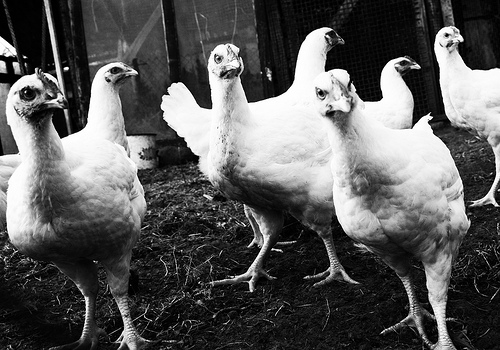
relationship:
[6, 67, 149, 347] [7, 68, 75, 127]
chicken has head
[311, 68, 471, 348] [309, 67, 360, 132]
chicken has head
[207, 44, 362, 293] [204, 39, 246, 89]
chicken has head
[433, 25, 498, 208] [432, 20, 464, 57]
chicken has head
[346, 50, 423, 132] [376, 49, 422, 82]
chicken has head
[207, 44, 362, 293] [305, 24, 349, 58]
chicken has head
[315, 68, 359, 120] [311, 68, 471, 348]
head of chicken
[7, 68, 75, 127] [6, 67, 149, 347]
head of chicken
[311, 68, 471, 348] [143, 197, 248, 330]
chicken on ground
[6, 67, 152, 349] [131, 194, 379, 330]
chicken on ground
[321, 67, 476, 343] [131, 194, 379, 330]
chicken on ground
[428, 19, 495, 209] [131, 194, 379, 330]
chicken on ground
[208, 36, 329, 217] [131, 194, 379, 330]
chicken on ground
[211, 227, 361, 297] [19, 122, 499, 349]
feet on ground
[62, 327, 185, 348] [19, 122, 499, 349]
chicken feet on ground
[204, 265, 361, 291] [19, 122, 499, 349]
chicken feet on ground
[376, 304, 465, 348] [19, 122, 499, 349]
chicken feet on ground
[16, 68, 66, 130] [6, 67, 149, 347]
head of chicken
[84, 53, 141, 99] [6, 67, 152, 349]
head of chicken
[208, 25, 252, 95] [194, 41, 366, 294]
head of chicken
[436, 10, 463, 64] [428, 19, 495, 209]
head of chicken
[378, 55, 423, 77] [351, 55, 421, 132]
head of chicken